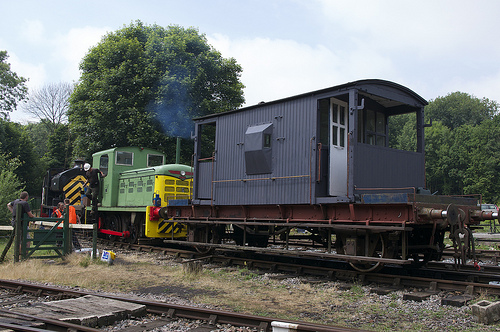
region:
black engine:
[220, 79, 417, 239]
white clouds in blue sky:
[240, 18, 301, 80]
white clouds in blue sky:
[433, 26, 478, 74]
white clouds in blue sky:
[340, 23, 365, 47]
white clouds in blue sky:
[16, 11, 68, 59]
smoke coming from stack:
[157, 91, 189, 166]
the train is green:
[102, 147, 167, 216]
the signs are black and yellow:
[64, 177, 92, 206]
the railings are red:
[302, 137, 322, 204]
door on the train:
[318, 101, 360, 216]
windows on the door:
[329, 110, 351, 156]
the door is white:
[327, 107, 351, 207]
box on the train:
[238, 118, 277, 169]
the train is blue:
[194, 113, 429, 217]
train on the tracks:
[186, 112, 475, 281]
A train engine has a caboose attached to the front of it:
[25, 68, 472, 328]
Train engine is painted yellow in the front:
[131, 158, 224, 262]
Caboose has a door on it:
[181, 93, 453, 246]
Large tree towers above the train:
[84, 15, 251, 249]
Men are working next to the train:
[11, 177, 125, 270]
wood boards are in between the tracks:
[19, 288, 144, 330]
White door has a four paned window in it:
[325, 95, 372, 204]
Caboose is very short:
[167, 81, 457, 303]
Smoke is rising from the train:
[139, 45, 271, 242]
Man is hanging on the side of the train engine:
[76, 158, 127, 225]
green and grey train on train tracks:
[81, 72, 499, 279]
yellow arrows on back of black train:
[60, 168, 94, 214]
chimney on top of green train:
[168, 127, 186, 161]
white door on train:
[324, 93, 359, 200]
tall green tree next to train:
[63, 13, 250, 172]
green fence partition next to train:
[11, 197, 78, 265]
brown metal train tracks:
[85, 233, 497, 294]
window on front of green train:
[111, 145, 165, 170]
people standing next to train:
[5, 183, 89, 255]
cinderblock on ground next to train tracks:
[467, 291, 497, 319]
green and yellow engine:
[69, 132, 199, 219]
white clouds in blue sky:
[259, 16, 293, 40]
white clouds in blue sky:
[25, 11, 52, 36]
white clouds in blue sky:
[249, 23, 309, 61]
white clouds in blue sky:
[429, 36, 456, 66]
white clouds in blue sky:
[330, 11, 368, 42]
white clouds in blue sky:
[376, 32, 423, 72]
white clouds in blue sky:
[237, 23, 287, 57]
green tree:
[407, 103, 494, 203]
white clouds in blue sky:
[263, 39, 295, 67]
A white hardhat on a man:
[80, 159, 91, 173]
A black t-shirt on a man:
[8, 200, 27, 222]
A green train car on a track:
[95, 145, 191, 208]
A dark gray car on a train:
[195, 76, 424, 202]